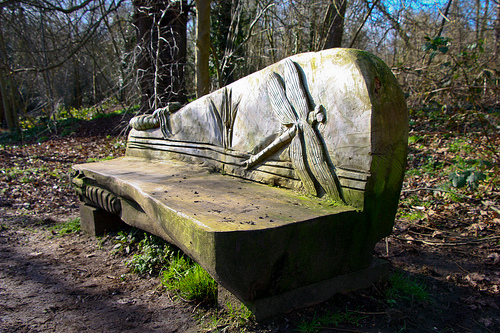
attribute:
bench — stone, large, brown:
[73, 46, 404, 323]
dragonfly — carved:
[244, 58, 345, 204]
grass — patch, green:
[158, 263, 218, 304]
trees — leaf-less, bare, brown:
[2, 2, 497, 120]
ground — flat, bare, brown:
[0, 113, 500, 323]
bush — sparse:
[4, 3, 500, 144]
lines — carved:
[126, 135, 372, 191]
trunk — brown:
[0, 87, 25, 147]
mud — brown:
[1, 140, 498, 326]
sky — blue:
[3, 2, 496, 46]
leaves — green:
[422, 33, 483, 61]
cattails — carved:
[203, 89, 238, 147]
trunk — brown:
[191, 3, 213, 93]